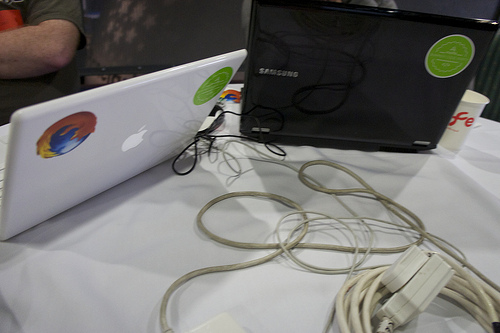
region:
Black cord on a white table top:
[170, 114, 291, 169]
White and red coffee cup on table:
[439, 85, 495, 159]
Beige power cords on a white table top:
[176, 179, 488, 331]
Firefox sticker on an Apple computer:
[31, 106, 107, 176]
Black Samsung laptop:
[250, 9, 471, 159]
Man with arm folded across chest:
[2, 7, 99, 85]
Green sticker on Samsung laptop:
[420, 28, 482, 93]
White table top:
[19, 251, 136, 322]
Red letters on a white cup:
[447, 108, 476, 133]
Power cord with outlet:
[366, 239, 453, 321]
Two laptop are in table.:
[46, 18, 465, 224]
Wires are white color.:
[184, 196, 456, 306]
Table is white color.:
[23, 224, 135, 302]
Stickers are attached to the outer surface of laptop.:
[21, 31, 457, 165]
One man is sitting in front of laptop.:
[15, 13, 107, 80]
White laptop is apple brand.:
[102, 111, 155, 171]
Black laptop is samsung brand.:
[253, 55, 345, 100]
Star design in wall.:
[102, 11, 171, 61]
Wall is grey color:
[168, 8, 243, 65]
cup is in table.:
[435, 83, 487, 186]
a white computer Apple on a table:
[5, 37, 241, 243]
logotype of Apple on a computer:
[115, 118, 153, 156]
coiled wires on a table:
[173, 143, 493, 331]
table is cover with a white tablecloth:
[51, 146, 497, 331]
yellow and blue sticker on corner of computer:
[30, 97, 100, 162]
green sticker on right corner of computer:
[183, 62, 240, 113]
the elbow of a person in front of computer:
[5, 6, 95, 81]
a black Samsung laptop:
[230, 0, 495, 151]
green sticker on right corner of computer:
[417, 25, 475, 80]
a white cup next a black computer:
[448, 84, 490, 165]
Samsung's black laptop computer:
[240, 0, 495, 150]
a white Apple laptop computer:
[0, 45, 245, 236]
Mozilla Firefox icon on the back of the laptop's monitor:
[33, 110, 98, 159]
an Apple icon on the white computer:
[119, 122, 150, 154]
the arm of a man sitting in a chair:
[1, 1, 86, 89]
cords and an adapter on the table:
[158, 161, 498, 331]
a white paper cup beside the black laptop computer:
[442, 90, 491, 152]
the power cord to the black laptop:
[171, 105, 286, 177]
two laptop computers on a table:
[2, 1, 498, 242]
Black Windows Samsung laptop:
[233, 10, 498, 135]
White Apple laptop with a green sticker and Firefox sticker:
[2, 45, 227, 242]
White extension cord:
[321, 205, 446, 330]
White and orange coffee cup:
[435, 85, 487, 168]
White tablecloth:
[93, 122, 494, 281]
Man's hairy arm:
[1, 21, 86, 78]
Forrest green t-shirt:
[18, 0, 94, 29]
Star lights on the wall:
[96, 2, 172, 57]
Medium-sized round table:
[0, 75, 499, 325]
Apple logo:
[116, 125, 155, 157]